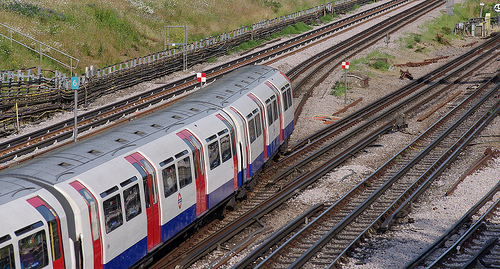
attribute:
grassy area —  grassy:
[0, 3, 319, 94]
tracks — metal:
[276, 18, 351, 45]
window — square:
[177, 150, 194, 188]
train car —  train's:
[3, 60, 303, 267]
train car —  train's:
[0, 174, 70, 267]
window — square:
[155, 159, 183, 197]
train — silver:
[2, 65, 294, 267]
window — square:
[174, 152, 199, 192]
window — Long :
[78, 185, 102, 242]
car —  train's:
[183, 49, 285, 154]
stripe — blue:
[188, 173, 256, 221]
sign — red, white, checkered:
[339, 60, 351, 70]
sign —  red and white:
[340, 61, 350, 69]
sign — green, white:
[58, 67, 88, 95]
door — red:
[124, 156, 178, 242]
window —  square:
[20, 235, 45, 265]